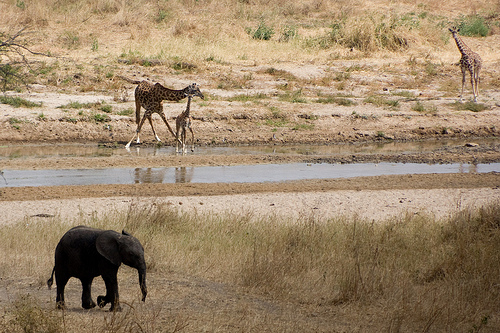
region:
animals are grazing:
[48, 91, 382, 296]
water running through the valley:
[287, 159, 413, 189]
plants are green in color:
[257, 19, 329, 41]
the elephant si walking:
[66, 215, 177, 327]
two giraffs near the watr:
[136, 69, 203, 150]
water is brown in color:
[232, 164, 323, 180]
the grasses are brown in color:
[188, 9, 245, 42]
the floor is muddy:
[281, 179, 380, 219]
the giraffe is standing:
[443, 20, 498, 104]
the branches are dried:
[311, 228, 462, 320]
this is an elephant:
[46, 225, 155, 307]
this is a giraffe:
[113, 82, 208, 140]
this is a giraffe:
[173, 96, 195, 141]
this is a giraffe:
[447, 25, 481, 96]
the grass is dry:
[397, 20, 425, 47]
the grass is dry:
[306, 228, 338, 263]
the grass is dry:
[441, 225, 483, 278]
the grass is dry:
[180, 214, 277, 275]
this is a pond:
[203, 164, 212, 181]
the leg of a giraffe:
[127, 110, 149, 147]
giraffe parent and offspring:
[126, 74, 206, 154]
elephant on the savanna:
[41, 219, 153, 315]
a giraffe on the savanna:
[444, 24, 486, 101]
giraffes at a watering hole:
[123, 73, 207, 155]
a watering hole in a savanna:
[2, 153, 498, 188]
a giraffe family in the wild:
[119, 21, 483, 155]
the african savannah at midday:
[3, 3, 444, 73]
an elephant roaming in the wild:
[44, 219, 154, 314]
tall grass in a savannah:
[292, 210, 493, 324]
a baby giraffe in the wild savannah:
[170, 89, 198, 155]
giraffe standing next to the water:
[445, 22, 490, 106]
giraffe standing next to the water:
[166, 89, 198, 156]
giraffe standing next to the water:
[120, 77, 210, 153]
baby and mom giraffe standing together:
[119, 78, 205, 152]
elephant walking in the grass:
[46, 223, 156, 314]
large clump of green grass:
[250, 15, 275, 44]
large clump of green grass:
[95, 101, 114, 116]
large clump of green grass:
[88, 111, 111, 123]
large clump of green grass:
[0, 90, 40, 107]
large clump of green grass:
[37, 109, 44, 121]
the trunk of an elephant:
[138, 258, 151, 298]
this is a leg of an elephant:
[107, 262, 117, 310]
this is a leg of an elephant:
[81, 282, 95, 315]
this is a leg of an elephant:
[52, 285, 66, 310]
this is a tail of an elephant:
[44, 267, 54, 291]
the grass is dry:
[340, 274, 369, 296]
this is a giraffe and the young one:
[130, 75, 210, 140]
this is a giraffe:
[444, 15, 486, 107]